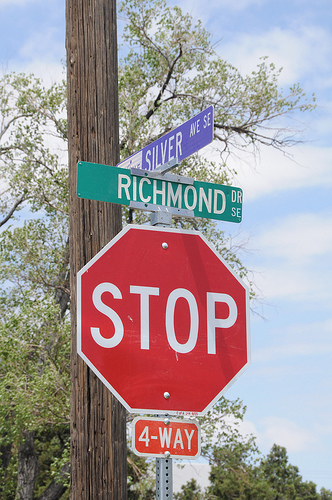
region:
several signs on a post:
[77, 92, 262, 498]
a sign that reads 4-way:
[122, 416, 208, 459]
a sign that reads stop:
[78, 209, 255, 421]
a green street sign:
[66, 159, 256, 227]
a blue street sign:
[103, 98, 230, 169]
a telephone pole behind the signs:
[54, 4, 127, 499]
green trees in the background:
[0, 1, 295, 433]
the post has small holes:
[154, 461, 176, 496]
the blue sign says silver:
[133, 126, 183, 169]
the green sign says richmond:
[109, 168, 230, 222]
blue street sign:
[111, 104, 231, 167]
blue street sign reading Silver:
[108, 103, 219, 165]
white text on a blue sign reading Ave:
[180, 118, 199, 133]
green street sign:
[73, 157, 243, 219]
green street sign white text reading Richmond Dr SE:
[75, 160, 246, 218]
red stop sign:
[73, 219, 246, 412]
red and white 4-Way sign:
[125, 416, 202, 455]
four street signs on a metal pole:
[71, 105, 254, 499]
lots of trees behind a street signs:
[1, 3, 329, 497]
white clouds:
[250, 207, 329, 313]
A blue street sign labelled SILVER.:
[132, 105, 224, 174]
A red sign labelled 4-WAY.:
[130, 414, 203, 460]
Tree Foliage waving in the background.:
[214, 430, 330, 498]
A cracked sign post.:
[68, 374, 123, 499]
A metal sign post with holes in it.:
[152, 459, 175, 497]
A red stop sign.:
[68, 223, 253, 420]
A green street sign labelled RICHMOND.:
[76, 160, 254, 224]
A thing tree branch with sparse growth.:
[125, 11, 197, 114]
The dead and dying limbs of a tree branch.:
[218, 116, 315, 176]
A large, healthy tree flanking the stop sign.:
[0, 239, 64, 498]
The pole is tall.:
[64, 0, 125, 498]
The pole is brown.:
[65, 0, 132, 496]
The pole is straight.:
[66, 0, 121, 499]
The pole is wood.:
[63, 0, 128, 499]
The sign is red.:
[72, 220, 253, 416]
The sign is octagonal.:
[68, 214, 254, 416]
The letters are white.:
[91, 276, 239, 360]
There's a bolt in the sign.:
[160, 236, 169, 249]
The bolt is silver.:
[158, 236, 171, 249]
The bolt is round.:
[156, 239, 170, 249]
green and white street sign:
[74, 159, 251, 218]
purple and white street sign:
[118, 111, 223, 167]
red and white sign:
[121, 414, 230, 476]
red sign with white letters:
[77, 248, 272, 392]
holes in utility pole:
[64, 364, 120, 452]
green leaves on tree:
[25, 363, 146, 494]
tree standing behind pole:
[29, 228, 170, 451]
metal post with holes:
[146, 459, 186, 497]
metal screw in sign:
[147, 382, 212, 421]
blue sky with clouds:
[201, 13, 323, 99]